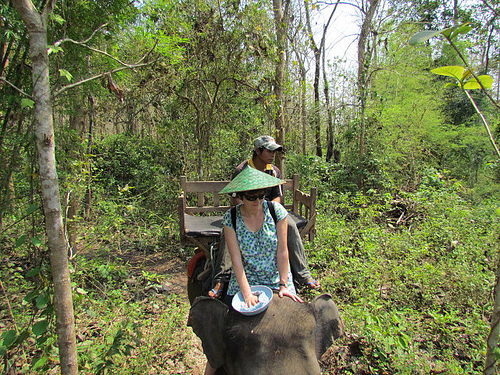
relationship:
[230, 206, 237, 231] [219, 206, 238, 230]
strap on shoulder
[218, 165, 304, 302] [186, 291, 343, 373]
lady riding elephant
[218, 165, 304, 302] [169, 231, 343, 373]
lady on elephant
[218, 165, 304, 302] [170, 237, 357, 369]
lady looks elephant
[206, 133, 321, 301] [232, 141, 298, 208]
man wears yellow shirt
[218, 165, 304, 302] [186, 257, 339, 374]
lady riding on elephant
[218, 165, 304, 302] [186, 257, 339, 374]
lady on back of elephant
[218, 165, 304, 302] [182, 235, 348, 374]
lady on elephant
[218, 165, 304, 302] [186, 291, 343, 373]
lady on elephant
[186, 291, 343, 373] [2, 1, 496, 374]
elephant in woods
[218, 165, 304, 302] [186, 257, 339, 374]
lady on elephant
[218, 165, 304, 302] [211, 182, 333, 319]
lady wearing blue top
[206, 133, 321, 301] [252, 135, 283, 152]
man wearing hat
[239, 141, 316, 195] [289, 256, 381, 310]
man wearing slippers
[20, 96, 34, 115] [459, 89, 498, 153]
leaf on branch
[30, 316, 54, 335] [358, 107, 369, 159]
leaf on branch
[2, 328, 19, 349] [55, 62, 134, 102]
leaf on branch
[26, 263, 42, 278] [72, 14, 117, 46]
leaf on branch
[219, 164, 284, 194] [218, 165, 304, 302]
hat on lady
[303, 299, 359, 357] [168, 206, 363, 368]
ear on elephant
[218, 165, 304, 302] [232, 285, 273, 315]
lady holding bowl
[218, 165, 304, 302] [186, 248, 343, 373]
lady on elephant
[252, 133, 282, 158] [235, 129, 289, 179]
hat on guy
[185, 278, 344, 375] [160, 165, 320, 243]
elephant on seat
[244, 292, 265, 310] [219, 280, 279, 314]
hand in bowl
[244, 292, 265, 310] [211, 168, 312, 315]
hand of lady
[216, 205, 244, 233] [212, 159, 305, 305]
shoulder of lady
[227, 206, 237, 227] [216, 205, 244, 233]
strap on shoulder